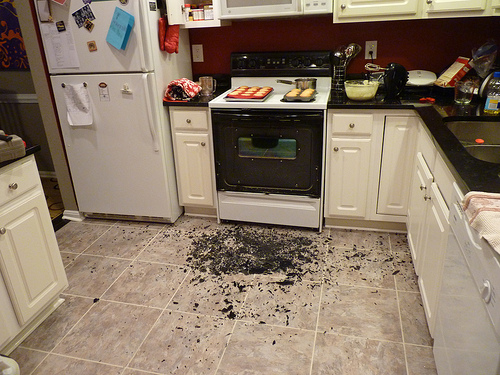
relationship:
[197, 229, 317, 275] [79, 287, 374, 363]
stuff on floor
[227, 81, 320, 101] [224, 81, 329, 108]
food on stove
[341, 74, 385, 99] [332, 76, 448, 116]
bowl on counter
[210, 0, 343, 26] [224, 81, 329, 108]
microwave above stove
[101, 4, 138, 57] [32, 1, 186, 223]
paper on fridge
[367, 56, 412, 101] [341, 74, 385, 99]
mixer next to bowl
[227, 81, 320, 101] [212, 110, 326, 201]
food on oven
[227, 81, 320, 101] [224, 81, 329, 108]
food on top stove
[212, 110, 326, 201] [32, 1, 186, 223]
oven near fridge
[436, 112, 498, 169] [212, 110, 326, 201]
sink near oven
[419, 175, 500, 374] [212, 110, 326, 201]
dishwasher near oven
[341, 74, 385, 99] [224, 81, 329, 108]
bowl near stove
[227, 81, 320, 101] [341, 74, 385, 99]
food near bowl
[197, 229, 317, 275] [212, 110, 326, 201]
stuff near oven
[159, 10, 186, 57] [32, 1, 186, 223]
mitts on fridge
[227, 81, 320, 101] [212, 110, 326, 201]
food over oven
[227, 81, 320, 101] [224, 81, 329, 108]
food on top of stove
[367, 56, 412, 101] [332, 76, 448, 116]
mixer on top of counter